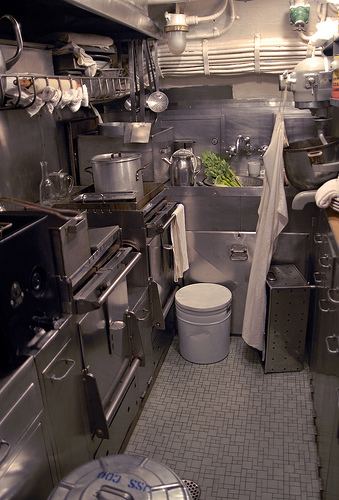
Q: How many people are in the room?
A: None.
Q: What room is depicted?
A: A kitchen.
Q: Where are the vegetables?
A: In a colendar in the sink.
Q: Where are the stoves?
A: On the left hand side of the photo.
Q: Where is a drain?
A: In the floor partially hidden by the silver trash can.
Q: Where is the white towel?
A: Hung over the oven door handle.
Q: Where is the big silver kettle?
A: On the stove closest to the sink.